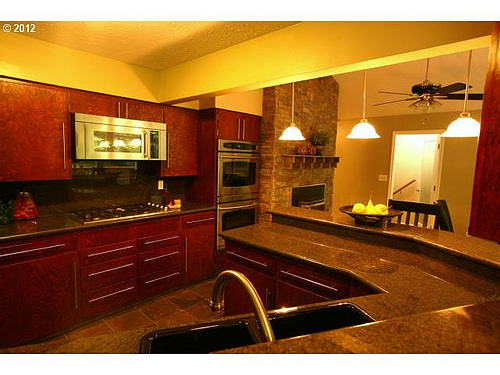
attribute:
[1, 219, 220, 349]
kitchen cabinets — brown, modern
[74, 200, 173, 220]
stovetop — under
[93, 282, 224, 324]
floor — dark, tiled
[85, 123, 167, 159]
microwave — stainless steel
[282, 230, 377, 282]
counter top — granite, beautiful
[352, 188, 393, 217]
fruit — deco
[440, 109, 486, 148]
lights — brightly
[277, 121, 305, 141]
light — descending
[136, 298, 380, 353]
sink — black, double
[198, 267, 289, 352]
faucet — silver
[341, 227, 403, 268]
counter top — granite